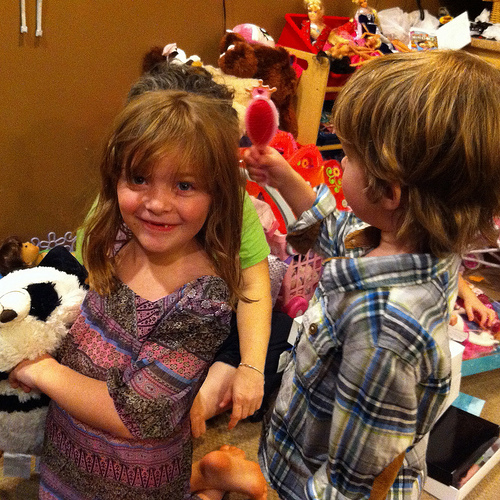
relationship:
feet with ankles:
[200, 445, 267, 497] [190, 457, 228, 498]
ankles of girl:
[190, 457, 228, 498] [9, 90, 240, 496]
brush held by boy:
[244, 96, 279, 154] [232, 42, 479, 496]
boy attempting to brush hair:
[232, 42, 479, 496] [62, 70, 258, 287]